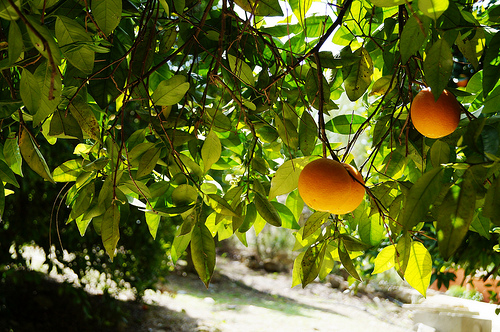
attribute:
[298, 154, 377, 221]
orange — round, hanging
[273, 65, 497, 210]
oranges — hanging, orange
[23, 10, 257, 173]
leaves — green, dark green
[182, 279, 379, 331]
road — brown, dirty, of dirt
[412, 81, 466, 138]
orange — hanging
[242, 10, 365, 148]
branch — brown